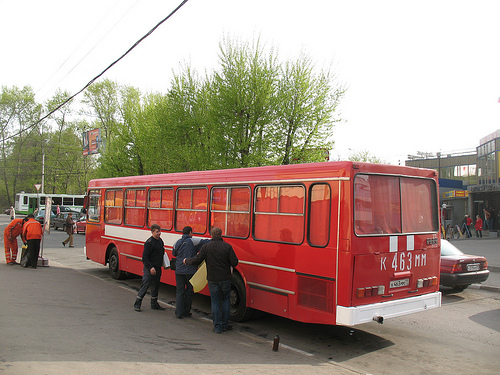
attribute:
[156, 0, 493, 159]
cloud — white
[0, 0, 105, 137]
cloud — white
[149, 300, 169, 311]
shoe — black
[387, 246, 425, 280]
numbers — white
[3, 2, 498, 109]
sky — blue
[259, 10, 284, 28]
sky — blue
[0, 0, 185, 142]
line — black 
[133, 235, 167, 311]
clothes — black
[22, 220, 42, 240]
jacket — neon-orange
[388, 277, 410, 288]
license plate — long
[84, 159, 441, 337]
bus — red, skinny, large , white 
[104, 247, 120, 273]
tire — black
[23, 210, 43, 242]
jacket — orange 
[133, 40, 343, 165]
tree — large, green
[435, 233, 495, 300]
car — burgundy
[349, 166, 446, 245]
rear window — large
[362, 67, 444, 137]
white clouds — white 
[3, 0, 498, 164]
blue sky — blue 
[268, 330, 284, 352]
bottle — brown, for drinking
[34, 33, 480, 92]
clouds — white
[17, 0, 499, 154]
sky — blue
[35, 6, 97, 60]
clouds — white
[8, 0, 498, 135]
sky — blue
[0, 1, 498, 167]
sky — blue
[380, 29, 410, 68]
cloud — white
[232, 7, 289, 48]
cloud — white